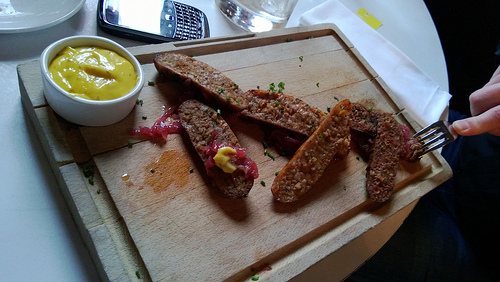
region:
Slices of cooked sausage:
[153, 48, 413, 208]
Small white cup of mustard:
[40, 30, 142, 127]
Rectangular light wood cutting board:
[15, 22, 452, 279]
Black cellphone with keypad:
[95, 0, 209, 44]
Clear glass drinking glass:
[215, 0, 299, 32]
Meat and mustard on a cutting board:
[17, 21, 452, 280]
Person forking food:
[407, 63, 498, 165]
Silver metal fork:
[410, 116, 463, 156]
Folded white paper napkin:
[300, 0, 452, 133]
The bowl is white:
[27, 15, 159, 135]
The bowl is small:
[30, 31, 141, 126]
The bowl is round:
[26, 30, 149, 124]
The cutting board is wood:
[16, 28, 463, 273]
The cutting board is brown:
[1, 28, 460, 278]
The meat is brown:
[176, 95, 261, 206]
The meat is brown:
[149, 42, 244, 108]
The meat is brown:
[357, 107, 406, 214]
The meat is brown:
[241, 85, 356, 151]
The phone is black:
[89, 0, 218, 47]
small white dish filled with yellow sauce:
[39, 33, 141, 125]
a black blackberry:
[98, 0, 210, 48]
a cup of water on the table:
[216, 0, 297, 36]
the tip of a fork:
[412, 119, 454, 159]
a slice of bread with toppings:
[176, 94, 256, 201]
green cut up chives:
[265, 82, 284, 90]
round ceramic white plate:
[0, 1, 87, 35]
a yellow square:
[355, 7, 382, 32]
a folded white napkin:
[297, 0, 452, 132]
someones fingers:
[452, 63, 498, 140]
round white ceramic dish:
[35, 28, 150, 130]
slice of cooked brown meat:
[174, 95, 261, 205]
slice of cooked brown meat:
[266, 94, 357, 205]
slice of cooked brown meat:
[362, 108, 408, 210]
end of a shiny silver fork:
[404, 114, 461, 162]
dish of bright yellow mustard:
[35, 32, 144, 114]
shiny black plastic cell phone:
[95, 0, 214, 49]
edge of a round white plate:
[2, 0, 92, 46]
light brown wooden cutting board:
[7, 22, 455, 280]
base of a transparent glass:
[210, 0, 299, 38]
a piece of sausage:
[362, 113, 402, 201]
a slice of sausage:
[270, 97, 350, 199]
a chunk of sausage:
[176, 100, 261, 196]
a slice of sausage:
[152, 49, 249, 112]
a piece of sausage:
[242, 89, 348, 156]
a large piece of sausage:
[346, 98, 421, 162]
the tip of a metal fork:
[410, 121, 458, 156]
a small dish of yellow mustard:
[41, 35, 142, 123]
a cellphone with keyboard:
[95, 1, 210, 41]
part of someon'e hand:
[451, 64, 498, 137]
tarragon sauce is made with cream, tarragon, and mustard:
[34, 25, 156, 133]